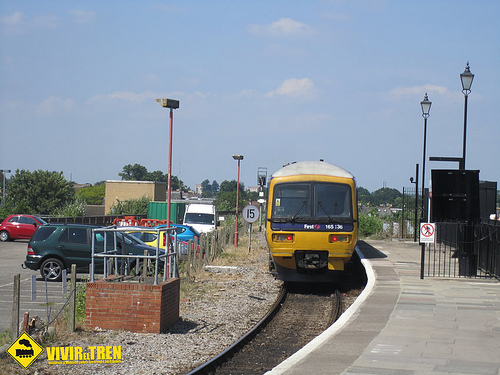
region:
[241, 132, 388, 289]
a yellow and white train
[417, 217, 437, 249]
a white, black and red sign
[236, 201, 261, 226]
a round sign with 15 on it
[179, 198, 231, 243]
a white van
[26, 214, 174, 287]
a green SUV is parked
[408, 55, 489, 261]
black poles with lights on top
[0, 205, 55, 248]
a parked red car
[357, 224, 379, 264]
shadow of train on ground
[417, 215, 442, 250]
sign says no walking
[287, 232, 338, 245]
two red lights on front of train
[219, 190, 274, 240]
a sign with the number 15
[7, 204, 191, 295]
a green mercedes suv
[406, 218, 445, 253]
a sign indicating pedestrians can't cross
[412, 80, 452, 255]
a tall black light post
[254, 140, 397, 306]
a yellow train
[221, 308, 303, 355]
a set of train tracks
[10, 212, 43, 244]
a small red car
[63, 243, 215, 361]
a small brick platform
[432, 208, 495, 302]
a black fence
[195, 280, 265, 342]
gravel beside the tracks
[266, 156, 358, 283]
gray and yellow train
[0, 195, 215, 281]
bunch of cars parked in the left side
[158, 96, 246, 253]
two red poles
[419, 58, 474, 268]
two large black lamppost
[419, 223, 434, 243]
red and white signboard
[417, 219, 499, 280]
small black fence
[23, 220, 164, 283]
green van in the parking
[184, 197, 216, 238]
white van in the parking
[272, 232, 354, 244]
two red front lights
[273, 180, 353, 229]
big windshield in the front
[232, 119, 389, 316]
Train going down the track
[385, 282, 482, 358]
Sidewalk beside the track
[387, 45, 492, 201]
Two tall lights on the sidewalk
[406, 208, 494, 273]
Gate on the sidewalk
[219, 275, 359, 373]
Track is beside the sidewalk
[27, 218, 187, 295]
Suv parking in the lot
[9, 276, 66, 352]
The parking lot has white lines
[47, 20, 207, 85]
The sky is blue with some clouds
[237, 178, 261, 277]
The speed limit sign says 15 on it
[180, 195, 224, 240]
White van parked in the lot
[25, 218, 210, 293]
green colored suv truck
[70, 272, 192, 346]
brick designed planter on gravel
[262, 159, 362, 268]
yellow train on road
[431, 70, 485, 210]
two lantern shaped street lights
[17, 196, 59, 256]
red small ford escort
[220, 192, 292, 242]
number 15 round sign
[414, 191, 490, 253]
black metal gate for protection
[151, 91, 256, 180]
square shaped street lights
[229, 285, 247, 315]
gravel area next to train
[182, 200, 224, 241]
white van in parking lot